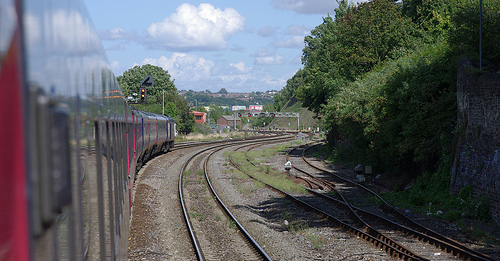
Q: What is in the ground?
A: Trees.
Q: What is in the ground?
A: Leafs.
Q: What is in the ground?
A: Stones.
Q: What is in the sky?
A: Clouds.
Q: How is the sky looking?
A: Clear.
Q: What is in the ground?
A: Trees.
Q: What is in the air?
A: Clouds.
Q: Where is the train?
A: On the rails.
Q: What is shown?
A: The side of a train.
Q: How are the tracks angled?
A: To the right.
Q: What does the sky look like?
A: Blue with white clouds.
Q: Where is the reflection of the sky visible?
A: In the upper left.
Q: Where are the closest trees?
A: On the right.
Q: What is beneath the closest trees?
A: Trash.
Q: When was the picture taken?
A: Day time.